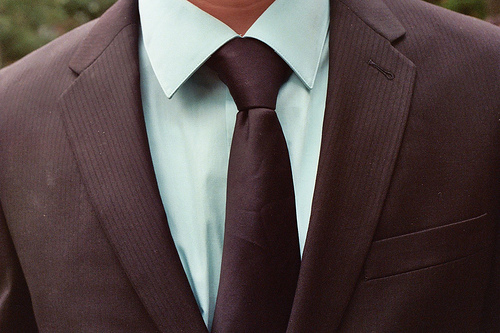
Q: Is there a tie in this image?
A: Yes, there is a tie.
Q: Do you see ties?
A: Yes, there is a tie.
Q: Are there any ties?
A: Yes, there is a tie.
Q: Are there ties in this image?
A: Yes, there is a tie.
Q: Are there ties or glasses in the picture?
A: Yes, there is a tie.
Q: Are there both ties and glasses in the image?
A: No, there is a tie but no glasses.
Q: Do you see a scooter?
A: No, there are no scooters.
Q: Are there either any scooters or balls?
A: No, there are no scooters or balls.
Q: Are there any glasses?
A: No, there are no glasses.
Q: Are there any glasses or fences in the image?
A: No, there are no glasses or fences.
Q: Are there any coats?
A: Yes, there is a coat.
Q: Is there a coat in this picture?
A: Yes, there is a coat.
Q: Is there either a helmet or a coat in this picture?
A: Yes, there is a coat.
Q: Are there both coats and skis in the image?
A: No, there is a coat but no skis.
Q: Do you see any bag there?
A: No, there are no bags.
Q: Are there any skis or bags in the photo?
A: No, there are no bags or skis.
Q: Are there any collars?
A: Yes, there is a collar.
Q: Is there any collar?
A: Yes, there is a collar.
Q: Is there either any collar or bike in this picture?
A: Yes, there is a collar.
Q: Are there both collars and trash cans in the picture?
A: No, there is a collar but no trash cans.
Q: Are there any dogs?
A: No, there are no dogs.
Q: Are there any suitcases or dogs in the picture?
A: No, there are no dogs or suitcases.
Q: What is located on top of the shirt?
A: The collar is on top of the shirt.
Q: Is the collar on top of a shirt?
A: Yes, the collar is on top of a shirt.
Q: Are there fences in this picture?
A: No, there are no fences.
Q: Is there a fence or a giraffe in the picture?
A: No, there are no fences or giraffes.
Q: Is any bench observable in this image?
A: Yes, there is a bench.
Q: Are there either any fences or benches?
A: Yes, there is a bench.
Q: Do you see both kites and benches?
A: No, there is a bench but no kites.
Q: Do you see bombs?
A: No, there are no bombs.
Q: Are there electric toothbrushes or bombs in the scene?
A: No, there are no bombs or electric toothbrushes.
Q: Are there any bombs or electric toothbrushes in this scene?
A: No, there are no bombs or electric toothbrushes.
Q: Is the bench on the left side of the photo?
A: Yes, the bench is on the left of the image.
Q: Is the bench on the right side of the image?
A: No, the bench is on the left of the image.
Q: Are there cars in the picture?
A: No, there are no cars.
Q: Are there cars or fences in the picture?
A: No, there are no cars or fences.